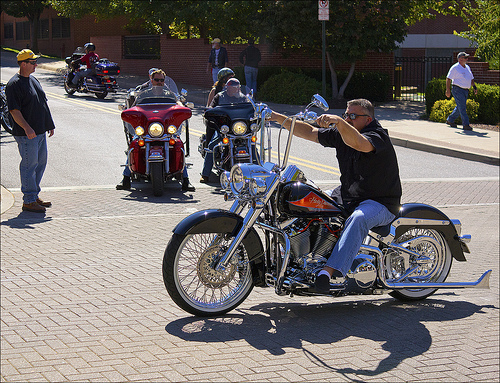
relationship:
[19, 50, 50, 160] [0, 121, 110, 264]
man on road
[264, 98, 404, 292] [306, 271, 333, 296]
man wearing shoes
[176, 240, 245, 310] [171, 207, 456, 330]
rim on tires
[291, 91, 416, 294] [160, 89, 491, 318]
man riding a bike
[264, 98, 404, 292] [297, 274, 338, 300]
man wearing shoes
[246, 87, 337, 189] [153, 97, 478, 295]
handles on a bike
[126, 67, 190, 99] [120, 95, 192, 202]
people riding a motorcycle